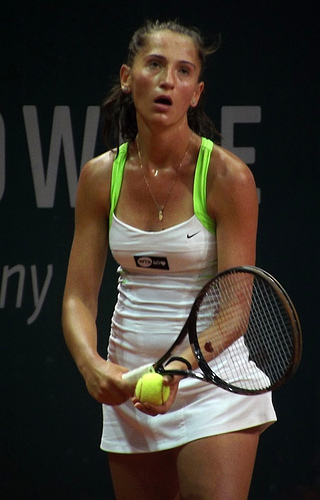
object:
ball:
[132, 369, 170, 406]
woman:
[61, 16, 284, 499]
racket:
[86, 258, 308, 414]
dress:
[94, 134, 281, 460]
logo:
[132, 249, 173, 272]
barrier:
[215, 1, 320, 276]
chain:
[133, 125, 192, 207]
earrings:
[123, 86, 130, 92]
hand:
[80, 361, 140, 411]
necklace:
[134, 128, 198, 224]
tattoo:
[199, 333, 223, 358]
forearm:
[178, 318, 265, 383]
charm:
[155, 208, 165, 222]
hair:
[101, 16, 220, 155]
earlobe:
[121, 81, 130, 95]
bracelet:
[166, 353, 194, 370]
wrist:
[166, 341, 205, 395]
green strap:
[109, 138, 134, 221]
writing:
[19, 96, 102, 218]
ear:
[113, 64, 136, 105]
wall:
[0, 12, 103, 444]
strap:
[191, 133, 224, 232]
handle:
[120, 360, 158, 393]